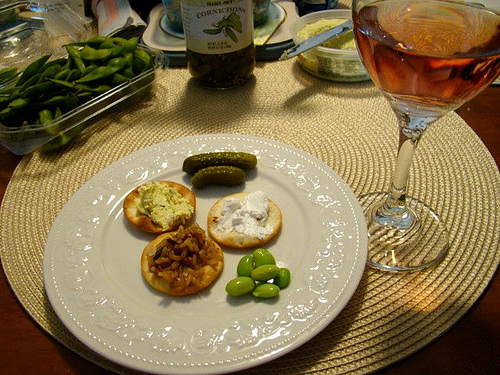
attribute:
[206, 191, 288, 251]
cracker — tan, brown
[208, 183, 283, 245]
substance — white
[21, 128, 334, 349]
plate — round, white, shiny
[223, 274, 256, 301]
lima bean — green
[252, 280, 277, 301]
lima bean — green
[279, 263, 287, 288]
lima bean — green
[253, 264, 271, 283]
lima bean — green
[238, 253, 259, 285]
lima bean — green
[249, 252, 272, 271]
lima bean — green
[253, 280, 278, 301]
bean — green lima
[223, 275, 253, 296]
bean — green lima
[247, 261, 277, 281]
bean — green lima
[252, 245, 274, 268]
bean — green lima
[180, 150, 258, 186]
pickles — green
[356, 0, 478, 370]
glass — clear, round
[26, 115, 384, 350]
plate — white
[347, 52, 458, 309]
glass — amber colored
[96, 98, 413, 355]
plate — white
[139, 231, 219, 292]
cracker — round, orange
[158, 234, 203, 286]
rice — brown